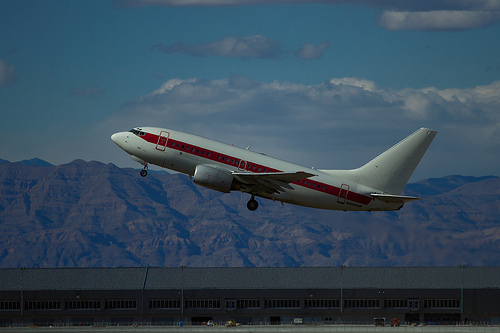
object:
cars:
[390, 316, 402, 327]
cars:
[224, 320, 241, 327]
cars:
[207, 319, 214, 327]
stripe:
[139, 131, 373, 205]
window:
[217, 155, 221, 160]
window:
[222, 156, 226, 160]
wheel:
[139, 169, 147, 177]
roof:
[0, 265, 499, 292]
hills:
[0, 160, 9, 268]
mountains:
[105, 210, 121, 219]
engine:
[191, 162, 237, 194]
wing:
[230, 170, 316, 194]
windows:
[261, 298, 302, 310]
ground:
[0, 323, 497, 333]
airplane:
[109, 126, 440, 213]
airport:
[0, 263, 500, 332]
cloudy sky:
[0, 0, 500, 183]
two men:
[19, 151, 74, 181]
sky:
[1, 0, 498, 182]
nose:
[110, 128, 133, 153]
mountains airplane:
[0, 210, 500, 267]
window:
[171, 142, 175, 146]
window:
[176, 143, 180, 147]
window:
[181, 145, 185, 149]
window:
[191, 147, 195, 152]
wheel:
[246, 199, 259, 212]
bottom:
[120, 145, 406, 212]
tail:
[357, 126, 439, 195]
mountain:
[0, 155, 500, 268]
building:
[0, 262, 500, 326]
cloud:
[38, 75, 500, 184]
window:
[196, 149, 200, 154]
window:
[202, 150, 205, 155]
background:
[0, 0, 500, 268]